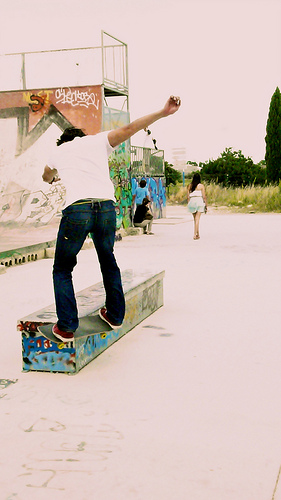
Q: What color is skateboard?
A: Black.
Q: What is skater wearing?
A: Pants.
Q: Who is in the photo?
A: Skater.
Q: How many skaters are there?
A: One.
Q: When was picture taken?
A: Daytime.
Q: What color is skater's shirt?
A: White.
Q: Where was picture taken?
A: Near ramp.